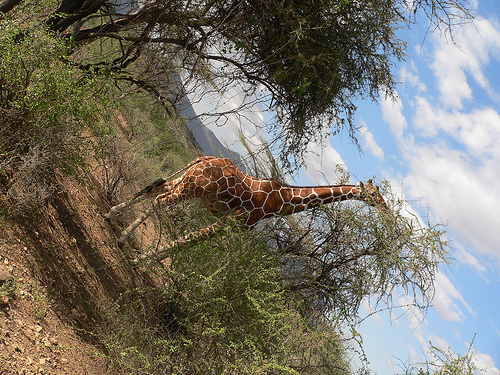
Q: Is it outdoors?
A: Yes, it is outdoors.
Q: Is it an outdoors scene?
A: Yes, it is outdoors.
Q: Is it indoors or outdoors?
A: It is outdoors.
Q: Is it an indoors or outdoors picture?
A: It is outdoors.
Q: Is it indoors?
A: No, it is outdoors.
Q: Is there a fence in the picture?
A: No, there are no fences.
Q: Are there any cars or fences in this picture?
A: No, there are no fences or cars.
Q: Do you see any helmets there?
A: No, there are no helmets.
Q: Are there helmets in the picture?
A: No, there are no helmets.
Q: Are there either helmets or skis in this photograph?
A: No, there are no helmets or skis.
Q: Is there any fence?
A: No, there are no fences.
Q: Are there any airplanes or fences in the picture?
A: No, there are no fences or airplanes.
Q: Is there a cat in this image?
A: No, there are no cats.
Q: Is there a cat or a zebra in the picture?
A: No, there are no cats or zebras.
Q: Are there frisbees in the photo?
A: No, there are no frisbees.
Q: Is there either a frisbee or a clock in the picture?
A: No, there are no frisbees or clocks.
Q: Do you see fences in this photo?
A: No, there are no fences.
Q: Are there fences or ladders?
A: No, there are no fences or ladders.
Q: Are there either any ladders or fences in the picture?
A: No, there are no fences or ladders.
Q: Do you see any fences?
A: No, there are no fences.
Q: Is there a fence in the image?
A: No, there are no fences.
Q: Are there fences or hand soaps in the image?
A: No, there are no fences or hand soaps.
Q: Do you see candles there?
A: No, there are no candles.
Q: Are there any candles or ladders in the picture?
A: No, there are no candles or ladders.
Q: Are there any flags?
A: No, there are no flags.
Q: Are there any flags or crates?
A: No, there are no flags or crates.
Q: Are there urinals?
A: No, there are no urinals.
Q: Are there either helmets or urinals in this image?
A: No, there are no urinals or helmets.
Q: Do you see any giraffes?
A: Yes, there is a giraffe.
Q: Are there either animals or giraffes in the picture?
A: Yes, there is a giraffe.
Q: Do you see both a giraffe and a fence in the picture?
A: No, there is a giraffe but no fences.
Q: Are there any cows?
A: No, there are no cows.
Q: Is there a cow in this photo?
A: No, there are no cows.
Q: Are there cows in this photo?
A: No, there are no cows.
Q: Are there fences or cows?
A: No, there are no cows or fences.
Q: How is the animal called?
A: The animal is a giraffe.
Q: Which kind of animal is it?
A: The animal is a giraffe.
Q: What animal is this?
A: This is a giraffe.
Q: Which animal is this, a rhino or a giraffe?
A: This is a giraffe.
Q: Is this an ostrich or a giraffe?
A: This is a giraffe.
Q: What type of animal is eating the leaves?
A: The animal is a giraffe.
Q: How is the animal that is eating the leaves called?
A: The animal is a giraffe.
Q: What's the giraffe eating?
A: The giraffe is eating leaves.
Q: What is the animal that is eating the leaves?
A: The animal is a giraffe.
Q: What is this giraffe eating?
A: The giraffe is eating leaves.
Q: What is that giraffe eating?
A: The giraffe is eating leaves.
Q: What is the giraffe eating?
A: The giraffe is eating leaves.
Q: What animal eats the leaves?
A: The animal is a giraffe.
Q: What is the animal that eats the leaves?
A: The animal is a giraffe.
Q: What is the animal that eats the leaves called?
A: The animal is a giraffe.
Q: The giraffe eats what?
A: The giraffe eats leaves.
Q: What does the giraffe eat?
A: The giraffe eats leaves.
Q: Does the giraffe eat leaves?
A: Yes, the giraffe eats leaves.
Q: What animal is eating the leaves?
A: The giraffe is eating the leaves.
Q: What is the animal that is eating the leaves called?
A: The animal is a giraffe.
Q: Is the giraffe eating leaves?
A: Yes, the giraffe is eating leaves.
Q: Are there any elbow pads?
A: No, there are no elbow pads.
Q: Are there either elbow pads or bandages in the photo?
A: No, there are no elbow pads or bandages.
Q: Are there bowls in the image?
A: No, there are no bowls.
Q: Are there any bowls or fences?
A: No, there are no bowls or fences.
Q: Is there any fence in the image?
A: No, there are no fences.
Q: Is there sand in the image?
A: Yes, there is sand.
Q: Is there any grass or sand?
A: Yes, there is sand.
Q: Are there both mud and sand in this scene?
A: No, there is sand but no mud.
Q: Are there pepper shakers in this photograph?
A: No, there are no pepper shakers.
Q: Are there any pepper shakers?
A: No, there are no pepper shakers.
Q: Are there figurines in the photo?
A: No, there are no figurines.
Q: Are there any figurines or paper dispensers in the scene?
A: No, there are no figurines or paper dispensers.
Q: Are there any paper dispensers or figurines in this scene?
A: No, there are no figurines or paper dispensers.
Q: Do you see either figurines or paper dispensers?
A: No, there are no figurines or paper dispensers.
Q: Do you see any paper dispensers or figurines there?
A: No, there are no figurines or paper dispensers.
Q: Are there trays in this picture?
A: No, there are no trays.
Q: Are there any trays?
A: No, there are no trays.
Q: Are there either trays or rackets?
A: No, there are no trays or rackets.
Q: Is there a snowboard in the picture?
A: No, there are no snowboards.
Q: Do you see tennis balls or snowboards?
A: No, there are no snowboards or tennis balls.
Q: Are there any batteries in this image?
A: No, there are no batteries.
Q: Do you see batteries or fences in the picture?
A: No, there are no batteries or fences.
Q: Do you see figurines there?
A: No, there are no figurines.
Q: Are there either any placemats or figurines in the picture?
A: No, there are no figurines or placemats.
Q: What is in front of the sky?
A: The clouds are in front of the sky.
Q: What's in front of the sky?
A: The clouds are in front of the sky.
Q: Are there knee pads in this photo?
A: No, there are no knee pads.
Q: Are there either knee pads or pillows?
A: No, there are no knee pads or pillows.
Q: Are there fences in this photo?
A: No, there are no fences.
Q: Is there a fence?
A: No, there are no fences.